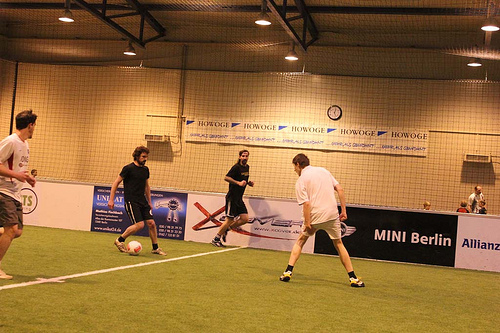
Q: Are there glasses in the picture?
A: No, there are no glasses.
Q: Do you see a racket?
A: No, there are no rackets.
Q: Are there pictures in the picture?
A: No, there are no pictures.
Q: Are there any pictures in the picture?
A: No, there are no pictures.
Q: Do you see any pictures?
A: No, there are no pictures.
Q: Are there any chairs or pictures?
A: No, there are no pictures or chairs.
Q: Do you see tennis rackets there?
A: No, there are no tennis rackets.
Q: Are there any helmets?
A: No, there are no helmets.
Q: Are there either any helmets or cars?
A: No, there are no helmets or cars.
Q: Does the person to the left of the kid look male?
A: Yes, the person is male.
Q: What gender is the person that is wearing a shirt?
A: The person is male.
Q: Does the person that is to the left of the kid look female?
A: No, the person is male.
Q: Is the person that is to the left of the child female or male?
A: The person is male.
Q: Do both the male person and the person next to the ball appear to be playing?
A: Yes, both the person and the person are playing.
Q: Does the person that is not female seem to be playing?
A: Yes, the person is playing.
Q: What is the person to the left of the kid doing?
A: The person is playing.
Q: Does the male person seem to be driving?
A: No, the person is playing.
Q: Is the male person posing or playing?
A: The person is playing.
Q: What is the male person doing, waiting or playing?
A: The person is playing.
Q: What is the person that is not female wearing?
A: The person is wearing a shirt.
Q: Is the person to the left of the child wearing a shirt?
A: Yes, the person is wearing a shirt.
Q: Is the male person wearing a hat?
A: No, the person is wearing a shirt.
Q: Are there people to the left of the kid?
A: Yes, there is a person to the left of the kid.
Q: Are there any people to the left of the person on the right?
A: Yes, there is a person to the left of the kid.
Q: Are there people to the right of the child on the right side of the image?
A: No, the person is to the left of the kid.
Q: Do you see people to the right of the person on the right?
A: No, the person is to the left of the kid.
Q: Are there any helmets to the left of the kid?
A: No, there is a person to the left of the kid.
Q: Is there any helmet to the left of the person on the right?
A: No, there is a person to the left of the kid.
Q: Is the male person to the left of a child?
A: Yes, the person is to the left of a child.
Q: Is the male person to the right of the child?
A: No, the person is to the left of the child.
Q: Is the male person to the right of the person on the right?
A: No, the person is to the left of the child.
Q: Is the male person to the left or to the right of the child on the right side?
A: The person is to the left of the child.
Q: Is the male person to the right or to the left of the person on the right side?
A: The person is to the left of the child.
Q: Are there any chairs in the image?
A: No, there are no chairs.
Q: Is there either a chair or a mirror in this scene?
A: No, there are no chairs or mirrors.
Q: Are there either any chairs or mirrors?
A: No, there are no chairs or mirrors.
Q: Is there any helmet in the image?
A: No, there are no helmets.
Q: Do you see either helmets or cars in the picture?
A: No, there are no helmets or cars.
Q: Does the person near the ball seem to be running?
A: Yes, the person is running.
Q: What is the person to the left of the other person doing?
A: The person is running.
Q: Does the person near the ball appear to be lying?
A: No, the person is running.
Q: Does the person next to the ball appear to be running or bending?
A: The person is running.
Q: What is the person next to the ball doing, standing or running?
A: The person is running.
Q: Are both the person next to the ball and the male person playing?
A: Yes, both the person and the person are playing.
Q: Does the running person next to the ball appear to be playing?
A: Yes, the person is playing.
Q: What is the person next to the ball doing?
A: The person is playing.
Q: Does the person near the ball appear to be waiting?
A: No, the person is playing.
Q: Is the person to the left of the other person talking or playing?
A: The person is playing.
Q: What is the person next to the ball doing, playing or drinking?
A: The person is playing.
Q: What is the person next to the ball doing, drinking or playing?
A: The person is playing.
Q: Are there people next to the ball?
A: Yes, there is a person next to the ball.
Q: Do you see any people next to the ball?
A: Yes, there is a person next to the ball.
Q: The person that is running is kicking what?
A: The person is kicking the ball.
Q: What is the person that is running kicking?
A: The person is kicking the ball.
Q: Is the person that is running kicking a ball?
A: Yes, the person is kicking a ball.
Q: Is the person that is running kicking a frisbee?
A: No, the person is kicking a ball.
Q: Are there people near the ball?
A: Yes, there is a person near the ball.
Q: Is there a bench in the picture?
A: No, there are no benches.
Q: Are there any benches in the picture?
A: No, there are no benches.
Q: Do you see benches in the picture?
A: No, there are no benches.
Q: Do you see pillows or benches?
A: No, there are no benches or pillows.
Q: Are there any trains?
A: No, there are no trains.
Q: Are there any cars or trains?
A: No, there are no trains or cars.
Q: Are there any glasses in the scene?
A: No, there are no glasses.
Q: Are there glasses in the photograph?
A: No, there are no glasses.